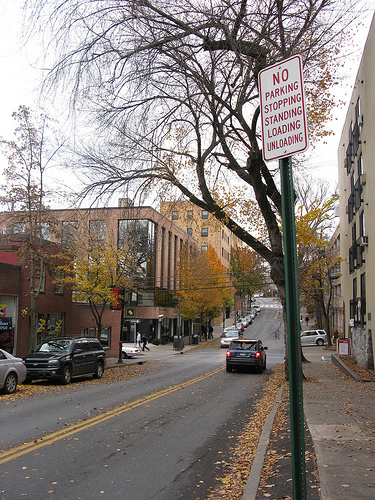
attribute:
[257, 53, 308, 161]
sign —  RED AND WHITE, street's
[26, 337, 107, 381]
car — black, parked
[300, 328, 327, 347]
car — white